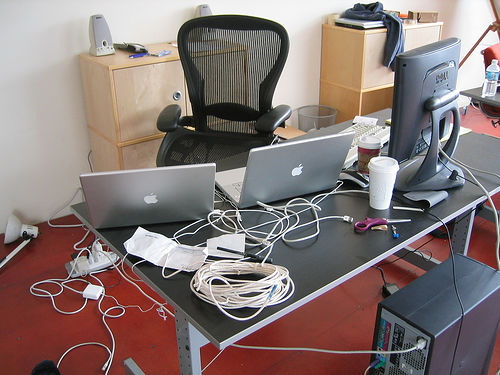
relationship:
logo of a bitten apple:
[284, 162, 310, 179] [297, 168, 305, 173]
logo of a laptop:
[284, 162, 310, 179] [242, 140, 355, 199]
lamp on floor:
[5, 211, 41, 251] [304, 317, 344, 335]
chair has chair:
[184, 26, 287, 111] [154, 13, 294, 168]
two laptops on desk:
[53, 136, 370, 221] [475, 135, 491, 166]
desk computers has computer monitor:
[385, 36, 466, 192] [386, 37, 465, 168]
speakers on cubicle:
[86, 11, 123, 57] [107, 60, 135, 79]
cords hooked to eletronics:
[249, 191, 348, 249] [242, 140, 355, 199]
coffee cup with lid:
[362, 150, 401, 214] [370, 155, 399, 173]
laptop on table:
[242, 140, 355, 199] [63, 216, 71, 225]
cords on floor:
[313, 190, 339, 213] [304, 317, 344, 335]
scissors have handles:
[351, 207, 419, 232] [344, 209, 386, 236]